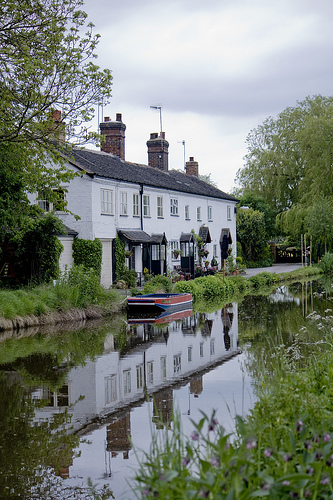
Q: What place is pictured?
A: It is a river.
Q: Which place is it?
A: It is a river.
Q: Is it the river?
A: Yes, it is the river.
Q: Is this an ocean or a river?
A: It is a river.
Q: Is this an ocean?
A: No, it is a river.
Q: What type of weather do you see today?
A: It is cloudy.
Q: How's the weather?
A: It is cloudy.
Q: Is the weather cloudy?
A: Yes, it is cloudy.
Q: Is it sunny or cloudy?
A: It is cloudy.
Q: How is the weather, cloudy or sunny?
A: It is cloudy.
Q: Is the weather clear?
A: No, it is cloudy.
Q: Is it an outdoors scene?
A: Yes, it is outdoors.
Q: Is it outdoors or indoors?
A: It is outdoors.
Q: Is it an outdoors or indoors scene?
A: It is outdoors.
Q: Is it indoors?
A: No, it is outdoors.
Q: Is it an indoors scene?
A: No, it is outdoors.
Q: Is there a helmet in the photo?
A: No, there are no helmets.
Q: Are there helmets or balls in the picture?
A: No, there are no helmets or balls.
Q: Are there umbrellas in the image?
A: No, there are no umbrellas.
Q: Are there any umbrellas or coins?
A: No, there are no umbrellas or coins.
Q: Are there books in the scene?
A: No, there are no books.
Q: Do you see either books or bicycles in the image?
A: No, there are no books or bicycles.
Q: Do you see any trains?
A: No, there are no trains.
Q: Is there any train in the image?
A: No, there are no trains.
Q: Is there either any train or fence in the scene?
A: No, there are no trains or fences.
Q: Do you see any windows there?
A: Yes, there is a window.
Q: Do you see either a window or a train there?
A: Yes, there is a window.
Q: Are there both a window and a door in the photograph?
A: Yes, there are both a window and a door.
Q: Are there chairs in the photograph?
A: No, there are no chairs.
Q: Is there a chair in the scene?
A: No, there are no chairs.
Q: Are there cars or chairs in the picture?
A: No, there are no chairs or cars.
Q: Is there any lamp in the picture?
A: No, there are no lamps.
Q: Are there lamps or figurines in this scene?
A: No, there are no lamps or figurines.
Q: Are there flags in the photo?
A: No, there are no flags.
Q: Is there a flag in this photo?
A: No, there are no flags.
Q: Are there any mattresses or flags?
A: No, there are no flags or mattresses.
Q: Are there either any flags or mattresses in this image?
A: No, there are no flags or mattresses.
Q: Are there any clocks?
A: No, there are no clocks.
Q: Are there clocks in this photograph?
A: No, there are no clocks.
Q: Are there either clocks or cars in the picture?
A: No, there are no clocks or cars.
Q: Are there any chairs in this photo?
A: No, there are no chairs.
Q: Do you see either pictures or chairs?
A: No, there are no chairs or pictures.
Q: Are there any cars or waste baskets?
A: No, there are no cars or waste baskets.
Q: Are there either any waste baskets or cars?
A: No, there are no cars or waste baskets.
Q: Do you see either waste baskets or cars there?
A: No, there are no cars or waste baskets.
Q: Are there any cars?
A: No, there are no cars.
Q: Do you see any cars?
A: No, there are no cars.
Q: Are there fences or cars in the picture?
A: No, there are no cars or fences.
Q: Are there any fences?
A: No, there are no fences.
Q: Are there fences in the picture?
A: No, there are no fences.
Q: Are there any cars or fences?
A: No, there are no fences or cars.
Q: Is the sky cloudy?
A: Yes, the sky is cloudy.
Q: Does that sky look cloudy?
A: Yes, the sky is cloudy.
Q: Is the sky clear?
A: No, the sky is cloudy.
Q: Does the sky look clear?
A: No, the sky is cloudy.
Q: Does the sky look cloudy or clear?
A: The sky is cloudy.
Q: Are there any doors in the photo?
A: Yes, there is a door.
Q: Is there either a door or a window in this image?
A: Yes, there is a door.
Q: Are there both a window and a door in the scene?
A: Yes, there are both a door and a window.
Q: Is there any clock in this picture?
A: No, there are no clocks.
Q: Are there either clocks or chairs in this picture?
A: No, there are no clocks or chairs.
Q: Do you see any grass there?
A: Yes, there is grass.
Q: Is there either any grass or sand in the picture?
A: Yes, there is grass.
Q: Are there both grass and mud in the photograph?
A: No, there is grass but no mud.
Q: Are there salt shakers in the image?
A: No, there are no salt shakers.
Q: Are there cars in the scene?
A: No, there are no cars.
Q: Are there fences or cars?
A: No, there are no cars or fences.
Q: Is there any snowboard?
A: No, there are no snowboards.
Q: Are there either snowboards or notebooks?
A: No, there are no snowboards or notebooks.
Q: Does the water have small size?
A: Yes, the water is small.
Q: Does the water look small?
A: Yes, the water is small.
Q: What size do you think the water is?
A: The water is small.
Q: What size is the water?
A: The water is small.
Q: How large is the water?
A: The water is small.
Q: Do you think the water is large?
A: No, the water is small.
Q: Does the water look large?
A: No, the water is small.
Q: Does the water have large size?
A: No, the water is small.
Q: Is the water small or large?
A: The water is small.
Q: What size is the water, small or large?
A: The water is small.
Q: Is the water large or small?
A: The water is small.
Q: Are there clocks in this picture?
A: No, there are no clocks.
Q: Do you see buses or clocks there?
A: No, there are no clocks or buses.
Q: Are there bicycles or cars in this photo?
A: No, there are no cars or bicycles.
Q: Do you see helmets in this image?
A: No, there are no helmets.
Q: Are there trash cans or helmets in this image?
A: No, there are no helmets or trash cans.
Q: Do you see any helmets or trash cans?
A: No, there are no helmets or trash cans.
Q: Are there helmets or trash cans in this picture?
A: No, there are no helmets or trash cans.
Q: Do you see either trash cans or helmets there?
A: No, there are no helmets or trash cans.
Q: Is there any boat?
A: Yes, there is a boat.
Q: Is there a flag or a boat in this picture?
A: Yes, there is a boat.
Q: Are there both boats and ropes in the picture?
A: No, there is a boat but no ropes.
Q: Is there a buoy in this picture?
A: No, there are no buoys.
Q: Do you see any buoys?
A: No, there are no buoys.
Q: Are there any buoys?
A: No, there are no buoys.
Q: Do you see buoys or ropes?
A: No, there are no buoys or ropes.